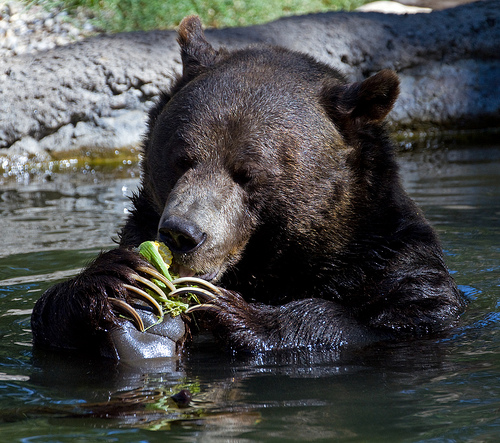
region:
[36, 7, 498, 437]
this is a very large beary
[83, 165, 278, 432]
the bear is eating something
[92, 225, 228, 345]
the bear has very long claws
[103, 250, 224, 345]
the claws are brown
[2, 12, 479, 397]
a brown bair in the water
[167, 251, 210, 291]
you can see the bear's tongue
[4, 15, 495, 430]
the bear has wet fur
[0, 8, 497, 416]
the bear has dark brown fur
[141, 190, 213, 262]
this is the bear's nose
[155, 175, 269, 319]
the snout of the bear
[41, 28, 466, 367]
a big bear sitting in the water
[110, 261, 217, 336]
the long claws on the bear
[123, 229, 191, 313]
the food the bear is eating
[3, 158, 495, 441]
the water the bear is sitting in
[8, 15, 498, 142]
the ground next to the water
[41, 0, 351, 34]
a green leafy plant in the back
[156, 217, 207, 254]
the big black nose of the bear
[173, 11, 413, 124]
the big ears of the bear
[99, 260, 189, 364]
the thing the bear is holding onto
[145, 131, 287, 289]
the calm face of the bear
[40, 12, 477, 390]
a bear in water eating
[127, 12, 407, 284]
the head of a bear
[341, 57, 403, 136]
the ear of a bear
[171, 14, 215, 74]
the ear of a bear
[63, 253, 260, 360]
the paws of a bear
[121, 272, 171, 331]
the claws of a bear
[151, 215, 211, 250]
the nose of a bear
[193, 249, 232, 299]
the mouth of a bear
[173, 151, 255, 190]
the eyes of a bear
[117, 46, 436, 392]
black color bear in the water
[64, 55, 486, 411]
bear holding something in the water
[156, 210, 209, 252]
nostrils of the black bear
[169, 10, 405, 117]
ear of the bear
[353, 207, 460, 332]
shoulder of the bear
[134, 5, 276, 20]
plants and trees near the water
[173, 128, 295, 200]
eyes of the bear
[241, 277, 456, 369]
front leg of the bear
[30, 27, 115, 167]
rock near the water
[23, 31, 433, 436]
the bear in the water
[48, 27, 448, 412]
the bear in the water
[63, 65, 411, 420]
the bear in the water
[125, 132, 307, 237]
bear's eyes are closed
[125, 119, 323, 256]
bear's eyes are closed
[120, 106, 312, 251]
bear's eyes are closed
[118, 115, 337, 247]
bear's eyes are closed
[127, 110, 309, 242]
bear's eyes are closed